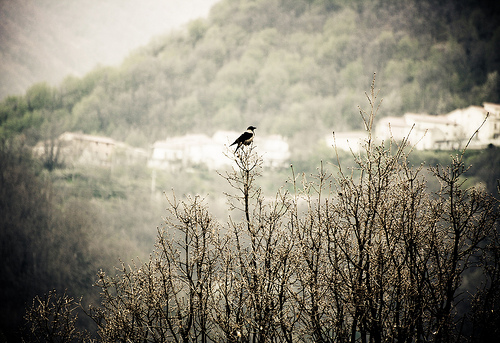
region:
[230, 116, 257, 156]
a black and white bird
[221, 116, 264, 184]
a black and white bird on a branch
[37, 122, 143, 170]
a large house on a hillside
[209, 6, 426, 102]
trees on a hilllside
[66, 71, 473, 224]
bird on tree near hillside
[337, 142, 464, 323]
dark tree branches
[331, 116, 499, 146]
large house on hillside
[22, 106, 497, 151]
three houses on hillside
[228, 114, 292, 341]
bird perched on large tree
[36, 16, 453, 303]
photo of houses and bird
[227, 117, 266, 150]
black bird on branch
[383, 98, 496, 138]
white building behind trees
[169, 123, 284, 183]
white building behind bird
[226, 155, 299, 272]
tree branch under bird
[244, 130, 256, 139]
white neck on bird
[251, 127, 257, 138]
white front on bird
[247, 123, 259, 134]
black head on bird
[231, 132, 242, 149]
black tail on bird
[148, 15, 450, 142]
large mountain behind bird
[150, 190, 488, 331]
brown trees under bird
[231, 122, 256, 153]
A balck and white bird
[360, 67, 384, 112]
The top of a tree branch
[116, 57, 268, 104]
A forest of trees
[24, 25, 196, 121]
A foggy mountain ridge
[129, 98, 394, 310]
A bird pirched atop a tree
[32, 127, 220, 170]
Some residential houses on a hill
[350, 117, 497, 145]
White houses on hill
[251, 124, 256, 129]
A birds front beak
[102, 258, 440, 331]
A barren dry bush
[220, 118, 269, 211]
A bird pirched atop a branch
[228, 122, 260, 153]
a black and white bird standing on a branch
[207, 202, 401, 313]
some branches with out any leaves on them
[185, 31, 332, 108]
a forest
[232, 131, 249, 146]
a bird wing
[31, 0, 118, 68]
a mountain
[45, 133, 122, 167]
a large house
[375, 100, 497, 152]
some houses in the distance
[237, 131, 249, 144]
the color black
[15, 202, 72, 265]
some bushes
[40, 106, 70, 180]
a tree with no leaves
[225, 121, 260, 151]
magpie on a tree branch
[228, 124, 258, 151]
black and white bird on a tree branch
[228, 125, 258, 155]
member of family corvidae on branch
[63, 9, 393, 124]
wooded area in elevation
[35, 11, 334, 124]
forest on a hillside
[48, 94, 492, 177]
a line of large homes on hillside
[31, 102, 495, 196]
homes on the mountainside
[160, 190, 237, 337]
very dense shrub with no leaves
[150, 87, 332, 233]
black and white bird in front of homes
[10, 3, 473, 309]
bird in the mountains near residences